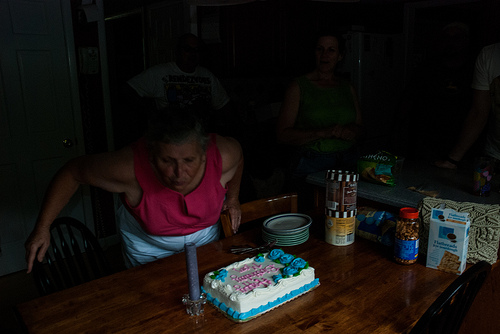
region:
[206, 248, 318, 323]
A birthday cake is on the table.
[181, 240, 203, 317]
A candle is on the table.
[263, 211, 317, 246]
Plates are on the table.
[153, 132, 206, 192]
A woman has blown out the candle.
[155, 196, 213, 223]
The shirt is pink.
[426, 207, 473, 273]
A box is on the table.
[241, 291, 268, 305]
The cake is white.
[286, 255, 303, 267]
The cake is blue.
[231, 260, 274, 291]
Writing is on the cake.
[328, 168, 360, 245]
Ice cream is on the table.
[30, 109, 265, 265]
a woman blowing out a candle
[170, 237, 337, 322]
a large birthday cake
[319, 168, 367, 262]
two cartons of ice cream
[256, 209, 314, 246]
a stack of small plates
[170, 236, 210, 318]
a large blue candle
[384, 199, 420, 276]
a jar of nuts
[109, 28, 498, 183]
several people at a birthday party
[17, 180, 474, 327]
a large wooden table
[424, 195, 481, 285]
a box of crackers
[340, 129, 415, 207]
a bag of chips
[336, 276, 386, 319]
a brown dining table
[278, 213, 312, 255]
plates on a table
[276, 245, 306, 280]
flowers on a cake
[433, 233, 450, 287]
a box on the table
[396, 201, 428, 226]
a red lid on a bottle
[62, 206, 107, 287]
a chair near the table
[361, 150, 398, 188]
a bag on the table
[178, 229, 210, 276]
a candle on a table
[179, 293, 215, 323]
candle holder on a table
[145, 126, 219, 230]
a woman in a red shirt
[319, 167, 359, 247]
Two containers of ice cream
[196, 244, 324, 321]
Blue and white cake with pink letters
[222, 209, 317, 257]
Pile of small plates and silver ware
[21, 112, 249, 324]
Woman in pink tank top blowing out candle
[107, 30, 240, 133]
Person wearing white shirt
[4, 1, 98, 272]
Closed white door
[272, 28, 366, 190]
Woman in green sleeveless top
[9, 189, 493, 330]
Three chairs and wood table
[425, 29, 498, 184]
Person wearing dark sandals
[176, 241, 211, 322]
Candle in glass holder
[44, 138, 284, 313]
an old woman blowing out a candle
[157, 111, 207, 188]
the head of an old woman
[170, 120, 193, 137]
the hair of an old woman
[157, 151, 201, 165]
the eyes of an old woman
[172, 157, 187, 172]
the nose of an old woman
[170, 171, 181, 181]
the mouth of an old woman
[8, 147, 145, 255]
the right arm of an old woman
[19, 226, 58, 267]
the right hand of an old woman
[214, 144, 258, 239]
the left arm of an old woman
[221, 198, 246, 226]
the left hand of an old woman